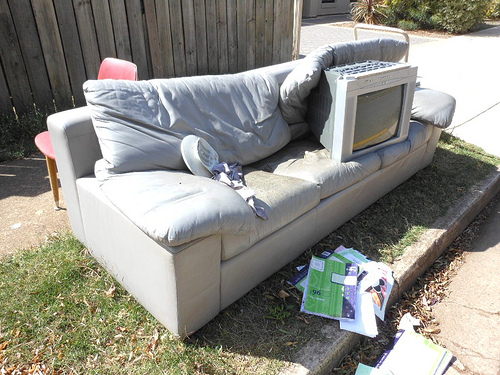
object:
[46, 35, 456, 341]
couch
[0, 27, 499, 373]
street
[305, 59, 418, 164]
television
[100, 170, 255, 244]
cushion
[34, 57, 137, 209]
chair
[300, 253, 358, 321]
paper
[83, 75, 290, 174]
pillow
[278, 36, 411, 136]
pillow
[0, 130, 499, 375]
grass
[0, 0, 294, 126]
fence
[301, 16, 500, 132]
driveway